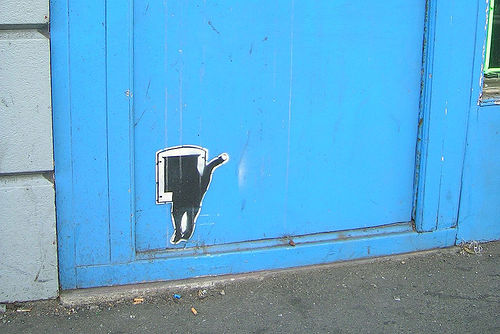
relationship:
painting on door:
[149, 141, 234, 250] [45, 3, 483, 289]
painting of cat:
[149, 141, 234, 250] [167, 150, 231, 247]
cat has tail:
[167, 150, 231, 247] [201, 152, 230, 192]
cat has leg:
[167, 150, 231, 247] [182, 206, 201, 243]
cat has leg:
[167, 150, 231, 247] [169, 201, 184, 244]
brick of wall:
[0, 1, 52, 34] [1, 7, 63, 309]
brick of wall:
[0, 26, 57, 179] [1, 7, 63, 309]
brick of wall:
[0, 173, 65, 308] [1, 7, 63, 309]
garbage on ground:
[124, 282, 233, 318] [0, 241, 497, 331]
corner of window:
[471, 70, 496, 110] [463, 2, 499, 116]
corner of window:
[396, 188, 433, 239] [463, 2, 499, 116]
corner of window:
[126, 227, 153, 267] [463, 2, 499, 116]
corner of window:
[49, 274, 69, 308] [463, 2, 499, 116]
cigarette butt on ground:
[190, 303, 197, 316] [0, 241, 497, 331]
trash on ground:
[15, 238, 491, 315] [0, 241, 497, 331]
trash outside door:
[15, 238, 491, 315] [45, 3, 483, 289]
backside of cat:
[179, 175, 203, 205] [161, 147, 233, 248]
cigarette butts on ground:
[125, 290, 199, 315] [0, 241, 497, 331]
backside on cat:
[147, 143, 237, 244] [106, 112, 255, 249]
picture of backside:
[154, 143, 228, 243] [147, 143, 237, 244]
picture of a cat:
[154, 143, 228, 243] [168, 152, 228, 242]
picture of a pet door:
[154, 143, 228, 243] [155, 145, 206, 201]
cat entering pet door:
[168, 152, 228, 242] [155, 145, 206, 201]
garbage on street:
[437, 239, 499, 266] [2, 232, 497, 329]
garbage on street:
[124, 282, 233, 318] [2, 232, 497, 329]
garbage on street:
[0, 305, 92, 315] [2, 232, 497, 329]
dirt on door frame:
[134, 219, 415, 261] [235, 215, 389, 252]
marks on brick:
[32, 267, 53, 284] [0, 173, 65, 308]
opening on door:
[156, 147, 205, 205] [38, 0, 483, 290]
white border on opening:
[153, 143, 208, 207] [149, 145, 222, 205]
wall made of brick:
[2, 3, 499, 302] [0, 26, 57, 179]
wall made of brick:
[2, 3, 499, 302] [0, 173, 65, 308]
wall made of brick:
[2, 3, 499, 302] [0, 0, 52, 34]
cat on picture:
[168, 152, 228, 242] [154, 143, 228, 243]